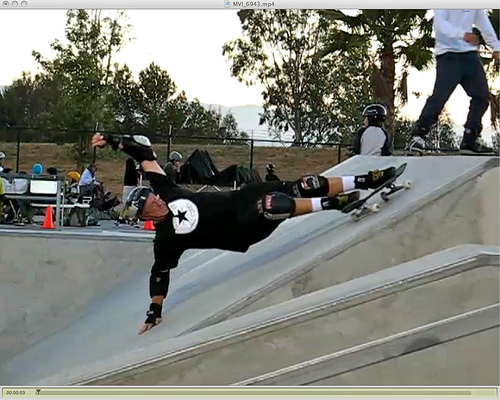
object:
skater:
[91, 129, 395, 336]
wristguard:
[145, 308, 153, 313]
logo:
[165, 197, 201, 235]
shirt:
[141, 171, 246, 270]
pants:
[419, 52, 489, 138]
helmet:
[121, 183, 153, 222]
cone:
[43, 204, 55, 228]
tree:
[0, 10, 248, 168]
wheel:
[402, 179, 412, 188]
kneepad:
[257, 192, 297, 217]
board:
[338, 161, 407, 214]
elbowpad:
[121, 131, 157, 163]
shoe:
[365, 166, 396, 188]